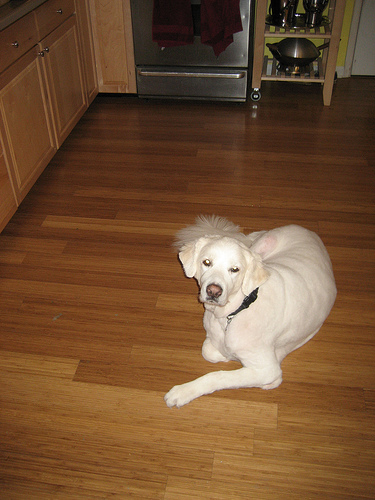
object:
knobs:
[11, 41, 19, 49]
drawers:
[0, 5, 41, 71]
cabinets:
[0, 0, 99, 233]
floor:
[4, 88, 373, 498]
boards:
[97, 113, 303, 201]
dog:
[163, 212, 338, 409]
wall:
[256, 0, 375, 83]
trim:
[343, 0, 360, 81]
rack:
[250, 0, 344, 109]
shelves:
[251, 0, 344, 107]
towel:
[152, 2, 249, 57]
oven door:
[127, 0, 255, 109]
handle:
[317, 38, 342, 51]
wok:
[266, 38, 321, 67]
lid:
[278, 38, 320, 59]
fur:
[274, 245, 324, 309]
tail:
[246, 230, 267, 242]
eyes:
[200, 257, 212, 269]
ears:
[177, 237, 208, 279]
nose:
[206, 271, 223, 299]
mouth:
[203, 296, 229, 311]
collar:
[224, 278, 269, 332]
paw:
[164, 374, 209, 408]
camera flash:
[204, 259, 212, 265]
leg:
[250, 227, 278, 258]